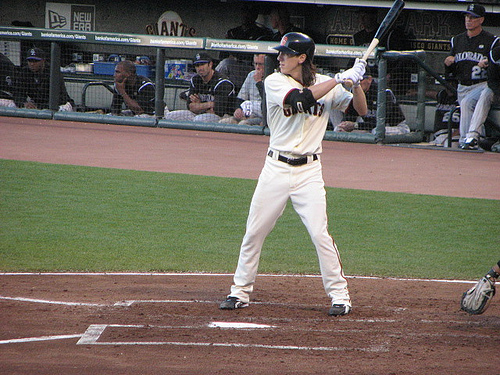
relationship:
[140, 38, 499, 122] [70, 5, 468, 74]
players in dugout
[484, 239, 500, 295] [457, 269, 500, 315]
catcher wearing glove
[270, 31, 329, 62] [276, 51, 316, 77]
helmet on head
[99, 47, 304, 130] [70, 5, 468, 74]
team in dugout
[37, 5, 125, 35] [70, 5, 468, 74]
sign in dugout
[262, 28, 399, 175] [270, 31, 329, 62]
batter wearing helmet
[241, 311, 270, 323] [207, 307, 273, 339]
dirt on home plate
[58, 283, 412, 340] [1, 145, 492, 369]
lines on field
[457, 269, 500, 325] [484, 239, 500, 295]
glove on catcher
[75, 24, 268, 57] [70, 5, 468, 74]
metal on dugout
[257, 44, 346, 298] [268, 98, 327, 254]
man wearing uniform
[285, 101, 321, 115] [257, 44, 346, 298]
elbow on man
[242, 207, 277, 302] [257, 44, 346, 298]
leg of man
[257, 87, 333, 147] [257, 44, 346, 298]
jersey on man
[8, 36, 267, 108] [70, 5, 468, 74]
people in dugout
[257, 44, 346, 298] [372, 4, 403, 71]
man holding bat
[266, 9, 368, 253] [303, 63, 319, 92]
player has hair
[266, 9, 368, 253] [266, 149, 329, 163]
player wearing belt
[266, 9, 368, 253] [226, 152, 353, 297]
player wearing trouser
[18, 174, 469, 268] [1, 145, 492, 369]
grass in field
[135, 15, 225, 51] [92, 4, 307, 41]
giants on wall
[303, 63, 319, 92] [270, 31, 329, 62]
hair under helmet